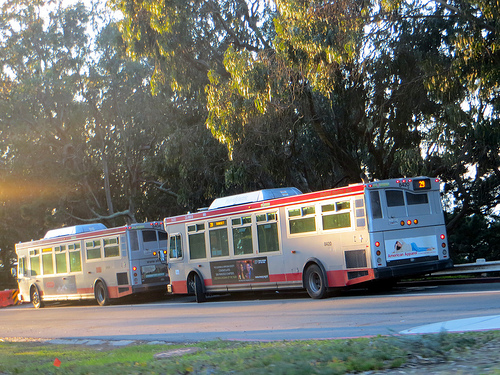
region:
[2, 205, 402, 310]
buses on the street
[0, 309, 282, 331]
sun on the street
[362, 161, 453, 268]
back of the bus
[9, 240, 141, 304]
side of the bus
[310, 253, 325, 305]
wheel of the bus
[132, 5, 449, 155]
the trees are massive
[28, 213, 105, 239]
top of the bus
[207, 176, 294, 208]
top of the bus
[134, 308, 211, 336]
shadow on the street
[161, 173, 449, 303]
a silver and red bus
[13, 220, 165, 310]
a silver and red bus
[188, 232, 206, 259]
a bus passenger window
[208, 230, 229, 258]
a bus passenger window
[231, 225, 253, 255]
a bus passenger window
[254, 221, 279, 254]
a bus passenger window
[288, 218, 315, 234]
a bus passenger window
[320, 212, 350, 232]
a bus passenger window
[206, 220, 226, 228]
an electric bus destination sign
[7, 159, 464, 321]
two buses on the road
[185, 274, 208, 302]
wheel is turned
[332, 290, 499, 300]
yellow line on the ground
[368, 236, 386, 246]
red light on the back of the bus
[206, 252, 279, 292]
advertisement on the side of the bus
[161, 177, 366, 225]
red stripe on the top of the bus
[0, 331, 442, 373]
green grass on the ground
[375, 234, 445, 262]
advertisement on the back of the bus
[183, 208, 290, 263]
four windows on the side of the bus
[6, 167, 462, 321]
Two buses are next to each other.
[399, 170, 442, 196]
The bus has a number on it.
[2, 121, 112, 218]
The sunlight is coming through the trees.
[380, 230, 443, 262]
Picture with a lady is on the bus.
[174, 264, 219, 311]
The bus' wheel is turned to the right.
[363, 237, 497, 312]
The guard rail is next to the bus.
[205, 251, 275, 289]
An advertisement is on the side of the bus.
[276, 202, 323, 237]
The window is closed.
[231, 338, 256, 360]
part of a ground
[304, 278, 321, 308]
part of a wheel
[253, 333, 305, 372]
part of a ground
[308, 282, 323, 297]
part fo a wheel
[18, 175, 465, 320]
Buses on the road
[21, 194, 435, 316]
Buses on the street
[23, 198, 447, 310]
Two buses on the road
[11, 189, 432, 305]
Two buses on the street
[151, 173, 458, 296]
Bus on the street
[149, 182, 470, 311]
Bus on the road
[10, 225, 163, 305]
Bus on the street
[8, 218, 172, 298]
Bus on the road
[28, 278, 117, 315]
Tires on the bus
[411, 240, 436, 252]
the woman on the poster is wearing jeans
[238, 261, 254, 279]
the couple on the poster are smiling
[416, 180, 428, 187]
the number 29 is orange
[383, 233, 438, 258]
the poster on the bus is white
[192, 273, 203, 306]
the tire on the bus is turned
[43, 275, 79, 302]
the poster on the bus is blue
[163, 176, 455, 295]
the bus is red and white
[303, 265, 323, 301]
the back tire is straight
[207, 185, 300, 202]
the storage on the roof is white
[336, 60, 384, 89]
green leaves on the tree